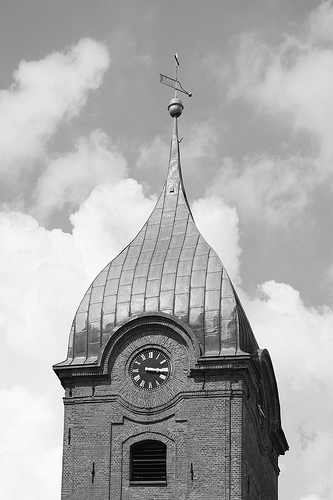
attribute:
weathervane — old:
[157, 49, 196, 118]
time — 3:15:
[137, 362, 169, 374]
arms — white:
[143, 364, 167, 374]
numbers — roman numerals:
[143, 347, 167, 365]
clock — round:
[126, 348, 174, 389]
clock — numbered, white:
[116, 333, 177, 388]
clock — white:
[109, 331, 177, 390]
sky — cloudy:
[25, 41, 318, 271]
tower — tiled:
[59, 159, 221, 326]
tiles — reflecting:
[44, 182, 247, 360]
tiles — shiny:
[59, 161, 284, 369]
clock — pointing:
[120, 345, 201, 417]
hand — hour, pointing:
[140, 362, 181, 380]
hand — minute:
[142, 360, 172, 378]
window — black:
[104, 431, 186, 496]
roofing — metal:
[88, 167, 272, 338]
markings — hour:
[144, 366, 172, 376]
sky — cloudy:
[17, 30, 330, 286]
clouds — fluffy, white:
[23, 82, 165, 281]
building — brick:
[59, 360, 245, 493]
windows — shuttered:
[113, 433, 183, 497]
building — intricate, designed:
[37, 95, 273, 486]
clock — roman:
[104, 342, 172, 406]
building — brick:
[49, 225, 242, 495]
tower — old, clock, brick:
[49, 50, 289, 498]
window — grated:
[126, 437, 169, 486]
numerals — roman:
[137, 350, 162, 361]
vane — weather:
[157, 49, 193, 99]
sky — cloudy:
[1, 1, 321, 498]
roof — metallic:
[50, 113, 292, 453]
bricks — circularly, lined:
[108, 326, 190, 408]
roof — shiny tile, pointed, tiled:
[51, 117, 260, 368]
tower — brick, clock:
[49, 115, 291, 497]